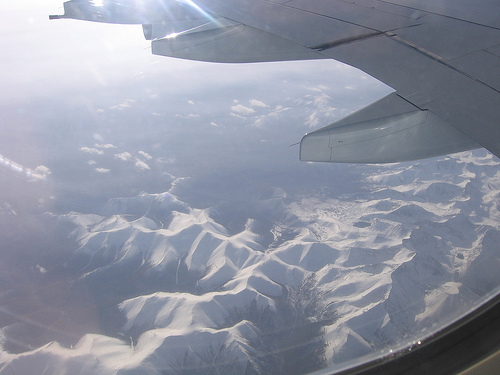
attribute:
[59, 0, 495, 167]
airplane wing — grey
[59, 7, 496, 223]
plane wing — grey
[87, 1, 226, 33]
light — reflecting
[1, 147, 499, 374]
snow — piled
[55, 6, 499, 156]
plane wing — white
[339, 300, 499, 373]
strip — black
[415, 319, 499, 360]
strip — black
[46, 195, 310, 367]
snow — piled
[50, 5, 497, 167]
wing — gray, small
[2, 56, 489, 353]
snow — frozen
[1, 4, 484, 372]
sky — white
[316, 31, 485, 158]
tile — rectangular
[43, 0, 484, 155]
plane wing — dark, white, gray, light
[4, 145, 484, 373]
mountain range — white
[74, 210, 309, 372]
mountain — white, large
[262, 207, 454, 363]
mountain — white, large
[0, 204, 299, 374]
mountain — white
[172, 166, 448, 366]
mountain — white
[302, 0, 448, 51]
roof — damaged